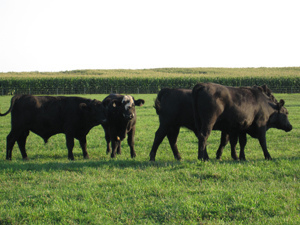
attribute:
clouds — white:
[208, 29, 261, 62]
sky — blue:
[208, 20, 259, 54]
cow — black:
[0, 87, 113, 171]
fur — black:
[233, 96, 257, 117]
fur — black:
[166, 96, 194, 117]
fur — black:
[103, 103, 121, 115]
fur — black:
[33, 99, 90, 127]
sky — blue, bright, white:
[5, 3, 299, 74]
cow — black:
[184, 74, 295, 167]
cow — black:
[197, 81, 291, 165]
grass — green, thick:
[155, 171, 248, 208]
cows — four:
[2, 77, 296, 165]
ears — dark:
[272, 97, 286, 112]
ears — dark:
[106, 95, 147, 110]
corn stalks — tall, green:
[119, 75, 140, 88]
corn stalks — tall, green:
[70, 75, 98, 90]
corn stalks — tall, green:
[274, 73, 294, 91]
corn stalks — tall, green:
[224, 75, 252, 84]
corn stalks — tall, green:
[170, 69, 194, 85]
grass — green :
[51, 163, 274, 223]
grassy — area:
[1, 93, 296, 224]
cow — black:
[96, 89, 150, 160]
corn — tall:
[1, 69, 298, 91]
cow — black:
[1, 92, 112, 160]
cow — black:
[138, 75, 293, 177]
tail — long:
[0, 93, 16, 115]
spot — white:
[123, 95, 132, 109]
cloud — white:
[96, 19, 157, 50]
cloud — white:
[38, 14, 131, 40]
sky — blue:
[150, 15, 281, 52]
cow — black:
[101, 94, 143, 157]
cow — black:
[157, 86, 237, 165]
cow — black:
[188, 79, 288, 158]